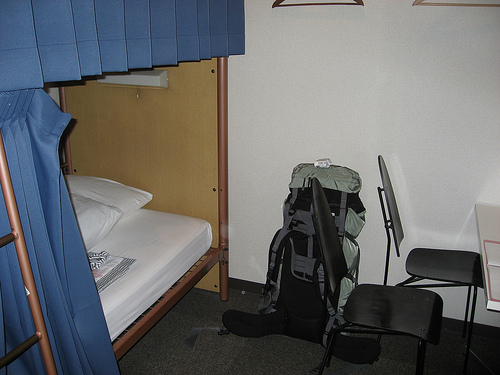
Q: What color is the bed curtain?
A: Blue.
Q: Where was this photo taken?
A: In a bedroom.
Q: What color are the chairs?
A: Black.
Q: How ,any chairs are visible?
A: Two.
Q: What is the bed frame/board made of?
A: Wood.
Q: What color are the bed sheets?
A: White.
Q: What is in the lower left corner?
A: Part of a ladder.